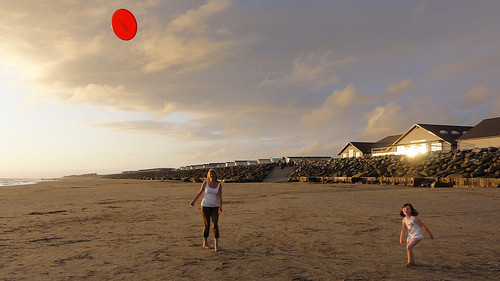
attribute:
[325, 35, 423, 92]
sky — blue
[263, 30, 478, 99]
sky — blue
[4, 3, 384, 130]
clouds — white 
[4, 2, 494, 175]
sky — blue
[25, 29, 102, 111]
clouds — white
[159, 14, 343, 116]
clouds — white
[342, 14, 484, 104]
clouds — white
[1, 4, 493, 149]
sky — blue 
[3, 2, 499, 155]
clouds — white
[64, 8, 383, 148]
clouds — white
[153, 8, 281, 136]
clouds — white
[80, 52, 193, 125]
clouds — white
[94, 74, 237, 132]
clouds — white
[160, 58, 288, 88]
clouds — white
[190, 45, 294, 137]
clouds — white